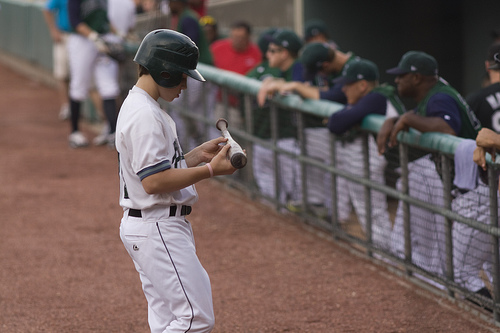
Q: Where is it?
A: This is at the field.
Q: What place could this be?
A: It is a field.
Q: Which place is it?
A: It is a field.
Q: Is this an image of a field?
A: Yes, it is showing a field.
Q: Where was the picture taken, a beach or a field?
A: It was taken at a field.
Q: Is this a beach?
A: No, it is a field.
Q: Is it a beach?
A: No, it is a field.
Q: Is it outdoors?
A: Yes, it is outdoors.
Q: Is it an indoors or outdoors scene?
A: It is outdoors.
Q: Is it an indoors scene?
A: No, it is outdoors.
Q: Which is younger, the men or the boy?
A: The boy is younger than the men.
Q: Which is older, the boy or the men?
A: The men is older than the boy.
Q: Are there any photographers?
A: No, there are no photographers.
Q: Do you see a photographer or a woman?
A: No, there are no photographers or women.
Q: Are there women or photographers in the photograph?
A: No, there are no photographers or women.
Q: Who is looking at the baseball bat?
A: The boy is looking at the baseball bat.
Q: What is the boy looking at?
A: The boy is looking at the baseball bat.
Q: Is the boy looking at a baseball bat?
A: Yes, the boy is looking at a baseball bat.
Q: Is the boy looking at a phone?
A: No, the boy is looking at a baseball bat.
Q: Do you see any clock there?
A: No, there are no clocks.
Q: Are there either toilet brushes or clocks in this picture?
A: No, there are no clocks or toilet brushes.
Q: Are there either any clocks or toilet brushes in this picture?
A: No, there are no clocks or toilet brushes.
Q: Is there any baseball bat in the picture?
A: Yes, there is a baseball bat.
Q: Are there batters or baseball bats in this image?
A: Yes, there is a baseball bat.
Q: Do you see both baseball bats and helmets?
A: Yes, there are both a baseball bat and a helmet.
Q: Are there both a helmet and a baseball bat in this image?
A: Yes, there are both a baseball bat and a helmet.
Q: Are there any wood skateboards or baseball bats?
A: Yes, there is a wood baseball bat.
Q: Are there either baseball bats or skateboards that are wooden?
A: Yes, the baseball bat is wooden.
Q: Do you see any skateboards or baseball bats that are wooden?
A: Yes, the baseball bat is wooden.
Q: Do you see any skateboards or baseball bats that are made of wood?
A: Yes, the baseball bat is made of wood.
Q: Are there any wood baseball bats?
A: Yes, there is a wood baseball bat.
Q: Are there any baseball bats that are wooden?
A: Yes, there is a baseball bat that is wooden.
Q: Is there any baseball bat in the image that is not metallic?
A: Yes, there is a wooden baseball bat.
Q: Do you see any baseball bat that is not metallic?
A: Yes, there is a wooden baseball bat.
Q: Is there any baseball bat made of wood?
A: Yes, there is a baseball bat that is made of wood.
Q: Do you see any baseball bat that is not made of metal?
A: Yes, there is a baseball bat that is made of wood.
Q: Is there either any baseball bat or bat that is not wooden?
A: No, there is a baseball bat but it is wooden.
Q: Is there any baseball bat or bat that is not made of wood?
A: No, there is a baseball bat but it is made of wood.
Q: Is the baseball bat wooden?
A: Yes, the baseball bat is wooden.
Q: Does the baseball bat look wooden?
A: Yes, the baseball bat is wooden.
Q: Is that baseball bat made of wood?
A: Yes, the baseball bat is made of wood.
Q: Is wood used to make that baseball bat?
A: Yes, the baseball bat is made of wood.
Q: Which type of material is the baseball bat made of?
A: The baseball bat is made of wood.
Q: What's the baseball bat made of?
A: The baseball bat is made of wood.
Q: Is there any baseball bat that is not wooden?
A: No, there is a baseball bat but it is wooden.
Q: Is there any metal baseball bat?
A: No, there is a baseball bat but it is made of wood.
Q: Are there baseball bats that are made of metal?
A: No, there is a baseball bat but it is made of wood.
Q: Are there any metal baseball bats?
A: No, there is a baseball bat but it is made of wood.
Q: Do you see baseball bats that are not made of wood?
A: No, there is a baseball bat but it is made of wood.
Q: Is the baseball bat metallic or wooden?
A: The baseball bat is wooden.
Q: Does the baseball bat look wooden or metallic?
A: The baseball bat is wooden.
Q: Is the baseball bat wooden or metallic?
A: The baseball bat is wooden.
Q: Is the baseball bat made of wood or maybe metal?
A: The baseball bat is made of wood.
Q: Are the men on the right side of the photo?
A: Yes, the men are on the right of the image.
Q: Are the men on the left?
A: No, the men are on the right of the image.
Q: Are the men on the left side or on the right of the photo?
A: The men are on the right of the image.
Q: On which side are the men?
A: The men are on the right of the image.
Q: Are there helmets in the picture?
A: Yes, there is a helmet.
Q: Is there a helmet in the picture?
A: Yes, there is a helmet.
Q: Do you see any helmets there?
A: Yes, there is a helmet.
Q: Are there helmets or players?
A: Yes, there is a helmet.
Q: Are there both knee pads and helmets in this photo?
A: No, there is a helmet but no knee pads.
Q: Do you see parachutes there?
A: No, there are no parachutes.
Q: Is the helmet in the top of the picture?
A: Yes, the helmet is in the top of the image.